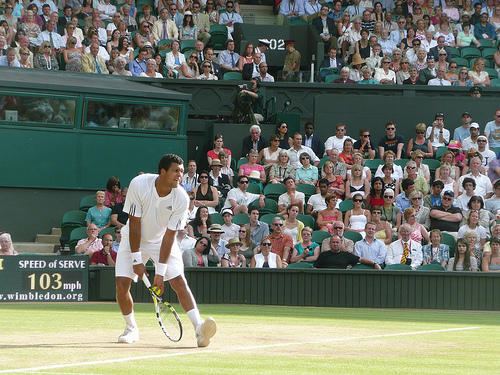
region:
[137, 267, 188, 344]
a white, black and yellow racket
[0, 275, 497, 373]
a green tennis court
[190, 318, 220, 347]
the shoe of a man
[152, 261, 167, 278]
a white wristband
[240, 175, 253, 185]
dark black sunglasses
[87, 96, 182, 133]
a window of a stadium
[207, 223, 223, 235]
a beige hat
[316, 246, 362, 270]
a man's black shirt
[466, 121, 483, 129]
a white baseball cap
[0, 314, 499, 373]
a long white line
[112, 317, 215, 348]
Man is wearing shoes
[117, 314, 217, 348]
Man is wearing white shoes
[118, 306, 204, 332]
Man is wearing socks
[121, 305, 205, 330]
Man is wearing white socks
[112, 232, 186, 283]
Man is wearing shorts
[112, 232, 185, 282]
Man is wearing white shorts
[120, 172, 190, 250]
Man is wearing a shirt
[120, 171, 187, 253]
Man is wearing a white shirt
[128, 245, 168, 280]
Man is wearing wrist bands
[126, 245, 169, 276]
Man is wearing white wrist bands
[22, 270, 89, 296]
Speed indicator of tennis ball serve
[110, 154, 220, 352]
Player about to serve tennis ball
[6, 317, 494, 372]
Grass tennis court of Wimbledon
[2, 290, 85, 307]
Wimbledon tournament website address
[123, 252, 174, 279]
White wristbands on tennis player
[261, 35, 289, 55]
Section number of stadium seating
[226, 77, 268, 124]
TV cameraman filming tennis match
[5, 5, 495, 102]
Spectators watching tennis match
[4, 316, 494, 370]
Boundary line of tennis court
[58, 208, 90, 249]
Empty green stadium seat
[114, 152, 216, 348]
Tennis player preparing for a serve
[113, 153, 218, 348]
Black tennis player preparing for a serve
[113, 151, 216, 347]
Colored tennis player preparing to serve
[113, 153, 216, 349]
Tennis player dressed in white shorts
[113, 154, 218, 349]
Tennis player dressed in a white t-shirt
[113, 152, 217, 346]
Tennis player dressed in white shorts and a white t-shirt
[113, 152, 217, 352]
Tennis player wearing white shoes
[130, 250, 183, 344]
Two hands holding a tennis racket and a tennis ball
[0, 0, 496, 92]
Upper balcony in a stadium filled with people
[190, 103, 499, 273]
Lower balcony in a stadium filled with people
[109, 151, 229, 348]
A tennis player.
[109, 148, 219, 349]
A man about to serve a tennis ball.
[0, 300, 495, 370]
A tennis court.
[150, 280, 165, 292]
A tennis ball.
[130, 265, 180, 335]
A black and yellow tennis racket with a white handle.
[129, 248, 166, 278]
White wristbands.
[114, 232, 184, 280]
A white pair of sports shorts.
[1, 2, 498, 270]
People watching the tennis match.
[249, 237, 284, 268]
A woman in a white vest wearing sunglasses.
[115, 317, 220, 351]
A white pair of tennis shoes.